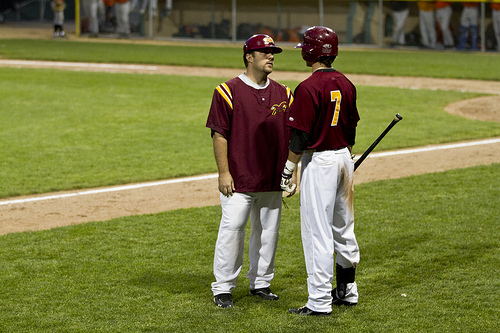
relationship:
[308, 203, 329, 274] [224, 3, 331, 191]
trousers of players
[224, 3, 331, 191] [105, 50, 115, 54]
players on grass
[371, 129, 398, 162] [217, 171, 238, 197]
bat in hand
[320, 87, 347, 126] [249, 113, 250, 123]
number on jersey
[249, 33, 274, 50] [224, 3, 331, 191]
cap on players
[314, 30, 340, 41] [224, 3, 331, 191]
helmet on players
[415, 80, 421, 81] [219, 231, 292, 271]
dirt on pants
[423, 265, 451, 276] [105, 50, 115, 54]
shadow on grass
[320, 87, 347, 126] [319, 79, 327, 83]
number on shirt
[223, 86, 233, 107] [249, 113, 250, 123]
stripe on jersey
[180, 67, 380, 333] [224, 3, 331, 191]
these are two baseball players